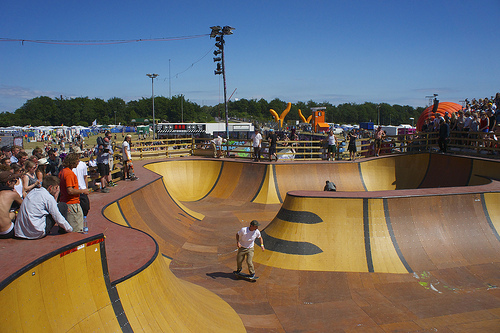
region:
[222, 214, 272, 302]
the man is skateboarding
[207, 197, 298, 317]
the man is skateboarding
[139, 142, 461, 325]
a yellow and brown ramp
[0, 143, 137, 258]
A crowd of people watching on the left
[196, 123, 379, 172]
A crowd of people watching directly behind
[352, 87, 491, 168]
A crowd of people watching on the right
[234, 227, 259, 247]
The skate boarders white t shirt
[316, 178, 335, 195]
A man in the bowl wearing a gray shirt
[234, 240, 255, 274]
The skate boarders khaki pants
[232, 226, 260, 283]
A man riding a skate board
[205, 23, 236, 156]
A lamp that is not lit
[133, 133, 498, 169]
A wooden fence in the distance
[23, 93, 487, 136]
Trees that are on the horizon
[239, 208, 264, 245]
the head of a woman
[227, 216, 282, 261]
a man wearing a white shirt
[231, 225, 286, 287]
aman wearing pants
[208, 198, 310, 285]
a man wearing a skateboard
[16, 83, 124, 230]
people watching someone on a sksteboard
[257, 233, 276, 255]
the arm of a man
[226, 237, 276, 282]
a man wearing pants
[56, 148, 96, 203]
a man wearing a orange shirt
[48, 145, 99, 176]
the hair of a man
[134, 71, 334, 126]
green leaves on a tree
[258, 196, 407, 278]
wood ramp painted yellow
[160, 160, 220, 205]
wood ramp painted yellow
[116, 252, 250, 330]
wood ramp painted yellow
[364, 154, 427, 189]
wood ramp painted yellow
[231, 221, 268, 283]
boy riding on skateboard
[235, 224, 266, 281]
man wearing tan pants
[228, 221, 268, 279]
man wearing long pants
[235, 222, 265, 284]
man wearing white shirt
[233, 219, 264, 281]
man wearing short sleeve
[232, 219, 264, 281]
man wearing black hat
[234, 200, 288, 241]
the head of a man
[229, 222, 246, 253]
the arm of a man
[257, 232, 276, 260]
the hand of a man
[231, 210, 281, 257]
the body of a man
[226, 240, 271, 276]
the legs of a man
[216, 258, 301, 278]
the feet of a man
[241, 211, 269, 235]
a man wearing a hat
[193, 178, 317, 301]
aman on a skateboard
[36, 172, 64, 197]
the hair of a man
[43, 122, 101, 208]
a man wearing a orange shirt